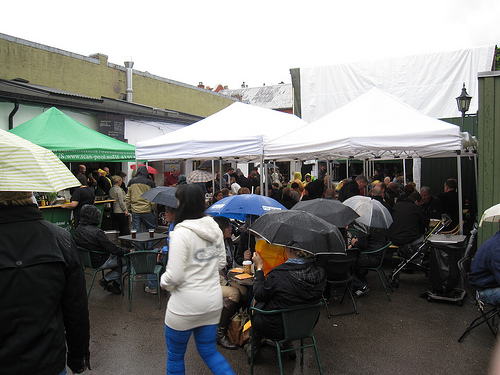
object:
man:
[73, 204, 133, 296]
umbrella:
[0, 129, 84, 194]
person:
[247, 246, 328, 366]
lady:
[159, 183, 236, 375]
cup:
[148, 229, 155, 239]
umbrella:
[247, 209, 348, 256]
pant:
[162, 325, 236, 375]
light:
[455, 82, 478, 126]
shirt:
[159, 213, 226, 332]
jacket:
[250, 261, 326, 340]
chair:
[248, 302, 324, 375]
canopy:
[5, 106, 149, 162]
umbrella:
[204, 186, 289, 227]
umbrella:
[134, 101, 308, 196]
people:
[337, 174, 369, 203]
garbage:
[426, 234, 468, 307]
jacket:
[159, 214, 227, 331]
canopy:
[260, 86, 478, 163]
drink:
[149, 229, 155, 239]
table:
[118, 232, 169, 293]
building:
[0, 32, 240, 188]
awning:
[260, 86, 479, 236]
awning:
[6, 106, 148, 172]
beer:
[131, 229, 155, 239]